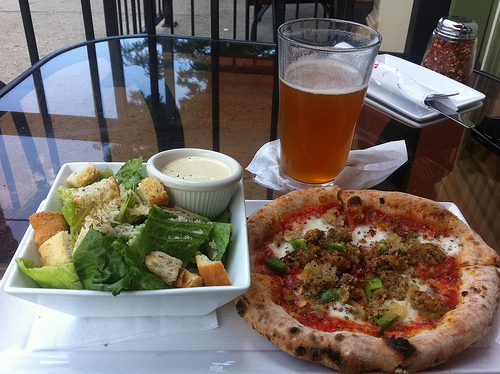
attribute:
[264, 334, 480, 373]
crust — brown, thick, burnt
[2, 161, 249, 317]
bowl — white, square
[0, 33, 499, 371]
table — glass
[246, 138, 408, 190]
napkin — white, crumpled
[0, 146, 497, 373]
meal — ready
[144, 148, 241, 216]
bowl — small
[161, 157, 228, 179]
dressing — cream color, white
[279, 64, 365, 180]
beverage — amber color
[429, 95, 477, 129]
silverwarre — rolled up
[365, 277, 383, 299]
pepper — green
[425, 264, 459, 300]
sauce — red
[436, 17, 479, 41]
lid — silver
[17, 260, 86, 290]
lettuce — green